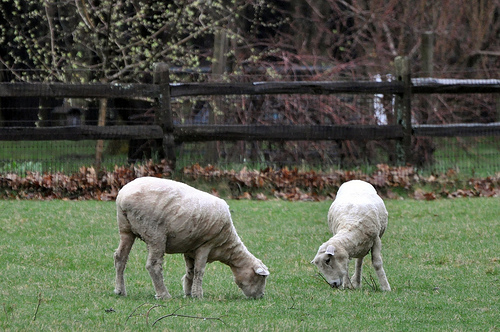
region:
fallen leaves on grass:
[405, 162, 496, 222]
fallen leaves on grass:
[416, 149, 470, 208]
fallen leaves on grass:
[413, 180, 451, 204]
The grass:
[323, 286, 329, 320]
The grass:
[285, 312, 306, 329]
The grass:
[305, 317, 326, 329]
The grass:
[300, 304, 336, 327]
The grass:
[289, 289, 327, 324]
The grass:
[290, 302, 320, 325]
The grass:
[313, 292, 389, 318]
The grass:
[281, 277, 363, 326]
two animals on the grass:
[155, 163, 405, 286]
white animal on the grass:
[85, 160, 295, 310]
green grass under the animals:
[265, 285, 310, 327]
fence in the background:
[222, 52, 318, 142]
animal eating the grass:
[55, 171, 286, 316]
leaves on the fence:
[263, 158, 330, 233]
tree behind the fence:
[53, 26, 153, 82]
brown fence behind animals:
[273, 58, 375, 158]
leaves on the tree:
[119, 17, 169, 59]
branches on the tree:
[23, 28, 149, 73]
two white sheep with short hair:
[68, 156, 412, 314]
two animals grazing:
[87, 156, 417, 306]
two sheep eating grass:
[92, 161, 405, 302]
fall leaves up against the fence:
[11, 165, 498, 199]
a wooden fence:
[0, 68, 499, 180]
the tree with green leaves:
[9, 11, 274, 167]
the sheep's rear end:
[91, 165, 189, 305]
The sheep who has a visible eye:
[313, 178, 404, 307]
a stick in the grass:
[120, 301, 233, 331]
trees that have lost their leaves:
[280, 6, 483, 165]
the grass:
[304, 292, 336, 317]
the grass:
[330, 316, 362, 329]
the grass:
[321, 300, 353, 325]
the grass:
[303, 300, 340, 330]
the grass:
[315, 272, 385, 327]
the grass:
[260, 233, 365, 311]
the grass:
[289, 269, 326, 321]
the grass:
[341, 282, 376, 324]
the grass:
[313, 270, 349, 327]